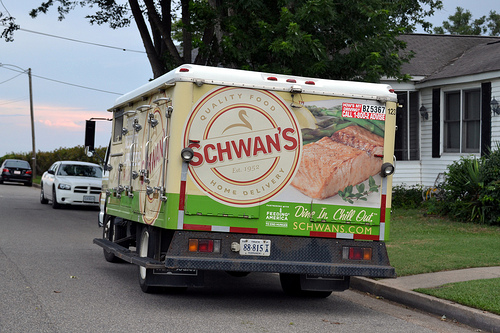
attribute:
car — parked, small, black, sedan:
[1, 157, 34, 185]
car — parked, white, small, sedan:
[39, 160, 104, 209]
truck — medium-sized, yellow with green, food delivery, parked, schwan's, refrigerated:
[85, 64, 403, 299]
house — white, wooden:
[342, 31, 499, 199]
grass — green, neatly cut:
[374, 206, 499, 313]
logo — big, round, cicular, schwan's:
[183, 86, 303, 209]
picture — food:
[289, 104, 386, 205]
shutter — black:
[430, 87, 442, 158]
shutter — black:
[480, 82, 491, 160]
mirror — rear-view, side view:
[83, 120, 96, 157]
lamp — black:
[417, 102, 428, 123]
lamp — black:
[489, 96, 499, 114]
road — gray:
[1, 179, 489, 332]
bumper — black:
[164, 231, 396, 278]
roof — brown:
[330, 32, 499, 83]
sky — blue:
[0, 1, 499, 158]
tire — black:
[104, 216, 128, 263]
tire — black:
[136, 224, 166, 292]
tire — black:
[279, 274, 333, 298]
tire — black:
[39, 182, 48, 205]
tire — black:
[52, 187, 60, 209]